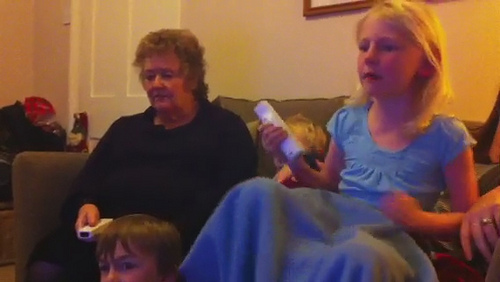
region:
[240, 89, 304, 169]
Wii mote in little girls hand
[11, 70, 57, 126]
Red flower by the wall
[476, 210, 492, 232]
wedding ring on finger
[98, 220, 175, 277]
head of a little boy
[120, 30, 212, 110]
Grandma sleeping instead of playing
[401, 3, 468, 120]
Blonde straight hair of girl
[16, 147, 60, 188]
Arm of sofa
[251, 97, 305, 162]
Wii controller in young girl's hand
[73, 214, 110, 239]
wii controller in older lady's hand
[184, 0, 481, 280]
young girl holding wii controller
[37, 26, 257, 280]
older lady holding wii controller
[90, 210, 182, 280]
young boy watching video games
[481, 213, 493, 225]
wedding band on hand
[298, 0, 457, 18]
framed picture hanging on wall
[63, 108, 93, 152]
bags hanging on door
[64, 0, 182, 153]
white wooden door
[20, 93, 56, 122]
red bag behind door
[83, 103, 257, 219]
the shirt is black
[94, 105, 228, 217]
the shirt is black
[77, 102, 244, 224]
the shirt is black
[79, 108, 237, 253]
the shirt is black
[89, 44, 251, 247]
grandma sitting on the couch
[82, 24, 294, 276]
grandma sitting on the couch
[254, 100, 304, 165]
a white Wii controller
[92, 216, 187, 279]
a little boy's head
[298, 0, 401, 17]
a framed picture on the wall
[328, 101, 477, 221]
the girl is wearing a blue shirt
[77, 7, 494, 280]
a group of people sitting together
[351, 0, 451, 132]
the girl has light hair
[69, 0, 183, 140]
the door is white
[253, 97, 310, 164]
a controller in a hand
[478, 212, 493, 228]
a gold ring on a finger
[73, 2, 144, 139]
a white door on a wall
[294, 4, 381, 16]
a picture on a wall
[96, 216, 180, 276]
a young childs head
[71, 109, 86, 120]
a brass door knob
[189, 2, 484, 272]
a young girl with blond hair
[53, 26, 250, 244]
a older lady holding a controller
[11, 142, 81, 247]
a tan couch arm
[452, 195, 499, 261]
a left hand of a person